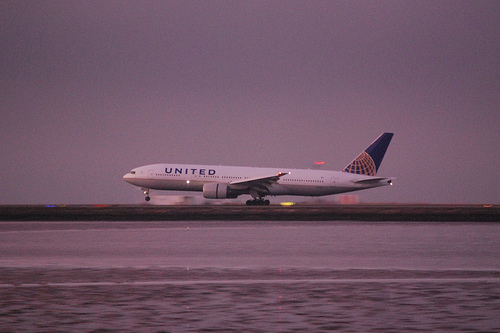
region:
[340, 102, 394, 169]
the tail is blue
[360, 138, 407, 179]
the tail is blue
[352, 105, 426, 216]
the tail is blue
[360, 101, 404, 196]
the tail is blue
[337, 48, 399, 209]
the tail is blue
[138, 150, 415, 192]
this is a jet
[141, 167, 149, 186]
the jet is white in color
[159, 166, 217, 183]
this is a writing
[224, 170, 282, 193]
this is a wing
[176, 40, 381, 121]
this is the sky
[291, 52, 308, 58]
the sky is blue in color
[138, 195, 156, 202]
this is the front wheels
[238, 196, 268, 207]
these are the back wheels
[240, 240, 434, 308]
this is a water body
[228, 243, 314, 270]
the water is calm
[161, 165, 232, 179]
The word United on the side of the plane.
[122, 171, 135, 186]
The nose of the plane.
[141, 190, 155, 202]
The front wheels of the plane.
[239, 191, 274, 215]
The wheels in the middle of the plane.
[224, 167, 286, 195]
The side wing of the plane.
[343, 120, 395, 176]
The tail of the plane.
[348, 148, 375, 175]
The design on the tail of the plane.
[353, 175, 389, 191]
The wing next to the tail of the plane.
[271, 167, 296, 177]
The lights on the side wing of the plane.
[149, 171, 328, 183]
The small passenger windows on the side of the plane.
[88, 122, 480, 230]
a commercial airliner above to land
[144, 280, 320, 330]
ripples on the surface of the water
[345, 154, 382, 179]
an orange grid on the tail fin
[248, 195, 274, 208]
black wheels on the plane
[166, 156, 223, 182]
blue letters on the plane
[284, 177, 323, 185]
windows in the plane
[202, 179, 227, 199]
a side engine on the plane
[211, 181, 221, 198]
a black stripe on the engine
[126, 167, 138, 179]
the windshield of the plane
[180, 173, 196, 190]
a light on the plane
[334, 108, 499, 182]
the logo of united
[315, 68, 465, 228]
the globe shape is yellow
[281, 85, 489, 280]
the globe is represented by curved lines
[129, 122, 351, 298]
united is the airline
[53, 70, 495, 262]
this is a large jet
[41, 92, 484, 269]
the plane is landing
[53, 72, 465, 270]
the plane is a 747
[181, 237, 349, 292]
the season is winter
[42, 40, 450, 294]
the time is dusk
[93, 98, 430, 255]
lights of the tower in background